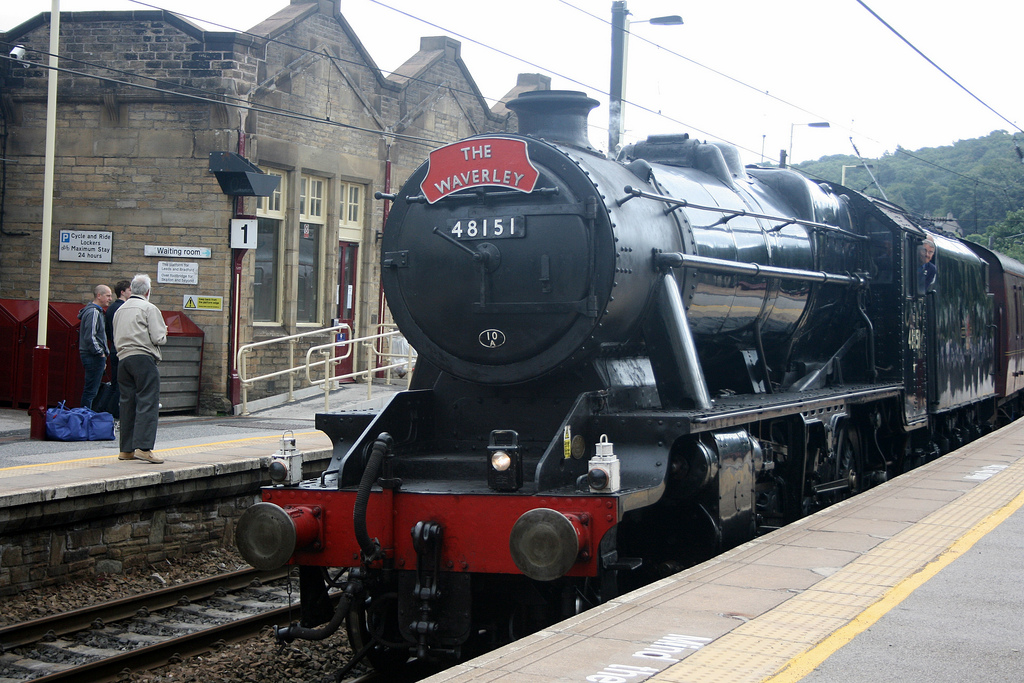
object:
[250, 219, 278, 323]
window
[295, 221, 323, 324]
window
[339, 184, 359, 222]
window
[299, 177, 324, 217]
window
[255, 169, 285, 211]
window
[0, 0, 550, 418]
building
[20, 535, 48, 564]
stone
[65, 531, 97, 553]
stone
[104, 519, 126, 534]
stone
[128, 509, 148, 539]
stone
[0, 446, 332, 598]
wall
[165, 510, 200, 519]
stone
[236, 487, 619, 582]
train bumper